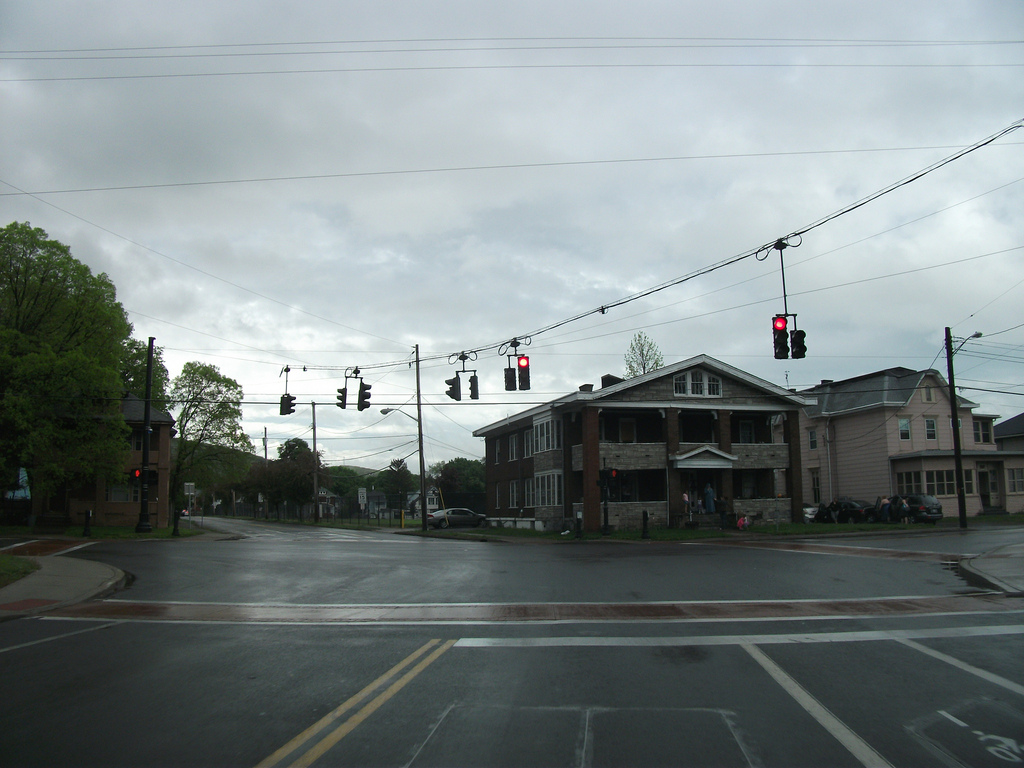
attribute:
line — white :
[740, 637, 883, 765]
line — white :
[455, 628, 1007, 659]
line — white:
[728, 579, 908, 755]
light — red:
[735, 231, 900, 487]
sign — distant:
[74, 350, 280, 681]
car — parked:
[372, 490, 504, 558]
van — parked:
[786, 438, 974, 585]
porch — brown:
[644, 453, 748, 588]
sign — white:
[296, 475, 437, 616]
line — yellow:
[190, 555, 432, 744]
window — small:
[652, 313, 745, 454]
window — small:
[901, 298, 949, 417]